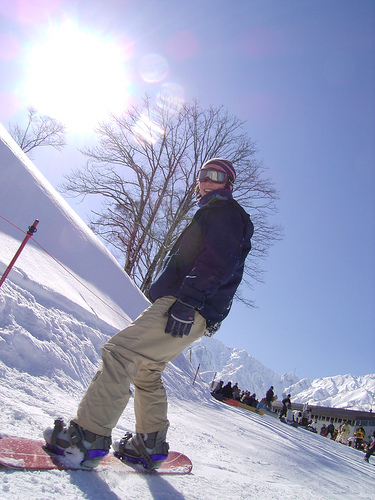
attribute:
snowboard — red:
[0, 432, 193, 470]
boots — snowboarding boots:
[71, 421, 227, 462]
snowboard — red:
[24, 426, 231, 478]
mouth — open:
[194, 175, 226, 202]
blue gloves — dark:
[167, 298, 192, 338]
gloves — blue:
[158, 295, 199, 337]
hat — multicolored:
[178, 146, 259, 196]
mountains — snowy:
[181, 329, 374, 419]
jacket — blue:
[146, 195, 256, 309]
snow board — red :
[0, 432, 192, 475]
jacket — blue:
[176, 200, 246, 314]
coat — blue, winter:
[144, 191, 254, 337]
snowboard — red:
[1, 129, 166, 296]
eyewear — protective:
[195, 168, 227, 183]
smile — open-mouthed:
[200, 188, 217, 199]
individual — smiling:
[48, 154, 253, 470]